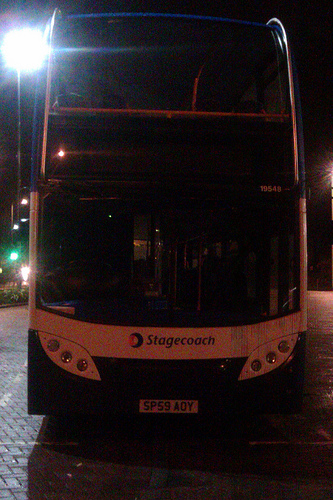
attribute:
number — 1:
[260, 183, 263, 191]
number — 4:
[271, 183, 276, 193]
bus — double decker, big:
[36, 8, 302, 431]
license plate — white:
[135, 386, 199, 415]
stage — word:
[143, 328, 181, 350]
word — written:
[143, 330, 220, 350]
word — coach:
[180, 332, 220, 346]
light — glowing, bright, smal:
[3, 25, 52, 76]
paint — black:
[29, 332, 307, 413]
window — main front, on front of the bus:
[61, 26, 279, 120]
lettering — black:
[138, 392, 195, 413]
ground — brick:
[3, 311, 330, 466]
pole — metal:
[7, 43, 36, 254]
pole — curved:
[193, 209, 214, 314]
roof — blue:
[45, 8, 292, 39]